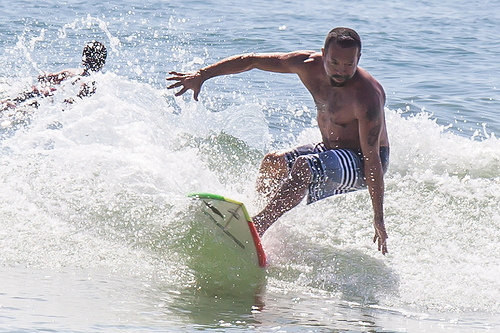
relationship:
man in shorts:
[167, 26, 390, 256] [284, 140, 370, 217]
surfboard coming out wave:
[186, 192, 269, 284] [6, 74, 495, 293]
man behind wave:
[167, 26, 390, 256] [0, 13, 500, 324]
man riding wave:
[167, 26, 390, 256] [0, 13, 500, 324]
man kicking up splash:
[167, 26, 390, 256] [0, 141, 238, 311]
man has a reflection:
[167, 26, 390, 256] [178, 279, 383, 331]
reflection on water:
[178, 279, 383, 331] [1, 3, 499, 332]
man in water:
[167, 26, 390, 256] [1, 3, 499, 332]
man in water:
[0, 41, 107, 114] [1, 3, 499, 332]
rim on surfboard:
[247, 217, 268, 264] [186, 192, 269, 284]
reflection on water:
[6, 153, 398, 333] [1, 3, 499, 332]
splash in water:
[7, 37, 499, 318] [1, 0, 498, 332]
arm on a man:
[162, 46, 311, 98] [167, 26, 390, 256]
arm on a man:
[357, 90, 397, 257] [167, 26, 390, 256]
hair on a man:
[324, 25, 365, 63] [167, 26, 397, 256]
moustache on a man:
[329, 68, 350, 84] [167, 26, 390, 256]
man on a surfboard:
[167, 26, 390, 256] [173, 191, 274, 311]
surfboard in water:
[186, 192, 269, 284] [1, 3, 499, 332]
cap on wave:
[17, 71, 498, 231] [7, 37, 499, 318]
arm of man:
[357, 90, 388, 256] [167, 26, 390, 256]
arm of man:
[167, 50, 312, 101] [167, 26, 390, 256]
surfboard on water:
[186, 192, 269, 284] [1, 3, 499, 332]